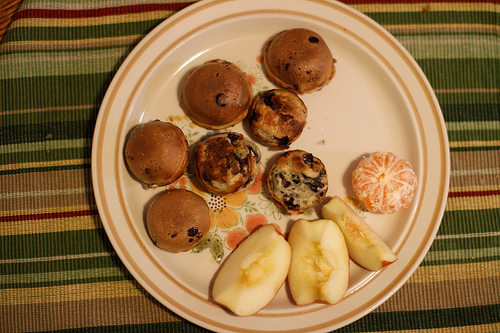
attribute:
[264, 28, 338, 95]
pancake — round, prepared, brown, cooked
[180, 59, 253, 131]
pancake — prepared, cooked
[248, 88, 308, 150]
pancake — prepared, cooked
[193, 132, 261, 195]
pancake — brown, white, prepared, cooked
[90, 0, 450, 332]
plate — white, orange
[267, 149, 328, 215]
pancake — blueberry, prepared, small, round, cooked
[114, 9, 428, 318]
line — orange, tan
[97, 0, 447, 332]
line — orange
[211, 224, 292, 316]
apple — white, cut, healthy, prepared, sliced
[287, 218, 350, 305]
apple — white, cut, healthy, prepared, sliced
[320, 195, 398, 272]
apple — white, cut, healthy, prepared, thin, sliced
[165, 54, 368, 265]
design — floral, orange, yellow, green, leafy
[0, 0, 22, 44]
table — brown, partially visible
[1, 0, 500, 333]
tablecloth — colorful, striped, green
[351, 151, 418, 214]
orange — healthy, prepared, small, peeled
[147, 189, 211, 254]
pancake — brown